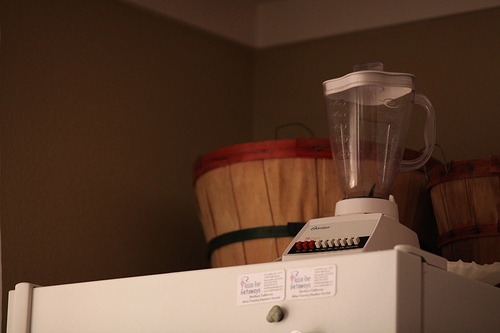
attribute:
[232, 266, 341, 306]
notes are written. — white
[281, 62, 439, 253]
there is a blender. — white, plastic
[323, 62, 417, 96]
there is a lid. — white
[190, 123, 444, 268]
there is a basket. — tan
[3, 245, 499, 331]
fridge is white. — white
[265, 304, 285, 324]
there is a magnet — rock shaped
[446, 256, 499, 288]
there are filters — white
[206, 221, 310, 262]
there is green — dark